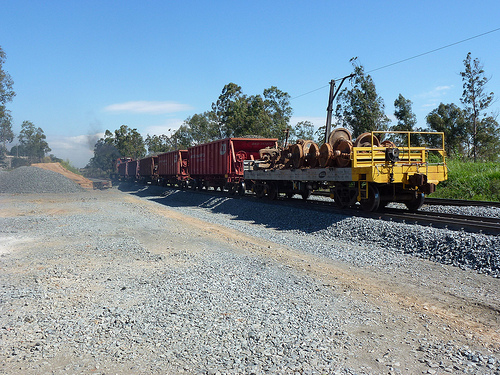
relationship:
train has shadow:
[158, 90, 458, 205] [281, 202, 337, 216]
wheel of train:
[304, 181, 387, 214] [158, 90, 458, 205]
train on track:
[158, 90, 458, 205] [240, 170, 362, 203]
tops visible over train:
[217, 79, 299, 120] [105, 131, 444, 213]